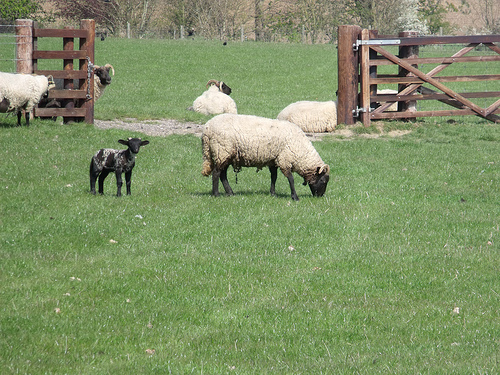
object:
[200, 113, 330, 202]
sheep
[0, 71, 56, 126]
sheep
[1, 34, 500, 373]
grass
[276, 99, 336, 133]
sheep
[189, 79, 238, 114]
sheep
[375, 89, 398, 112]
sheep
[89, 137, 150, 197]
sheep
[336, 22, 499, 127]
fence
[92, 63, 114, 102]
sheep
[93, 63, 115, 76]
horns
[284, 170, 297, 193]
leg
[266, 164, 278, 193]
leg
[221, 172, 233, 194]
leg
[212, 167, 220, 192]
leg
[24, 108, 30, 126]
leg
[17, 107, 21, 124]
leg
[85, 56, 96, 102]
chain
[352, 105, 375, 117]
hinge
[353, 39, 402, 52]
hinge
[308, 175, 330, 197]
face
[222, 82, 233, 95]
face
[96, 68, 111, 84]
face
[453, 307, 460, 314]
flower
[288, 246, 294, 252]
flower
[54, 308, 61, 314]
flower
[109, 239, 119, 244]
flower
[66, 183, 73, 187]
flower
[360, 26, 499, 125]
gate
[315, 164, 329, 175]
ear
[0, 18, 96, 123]
fence